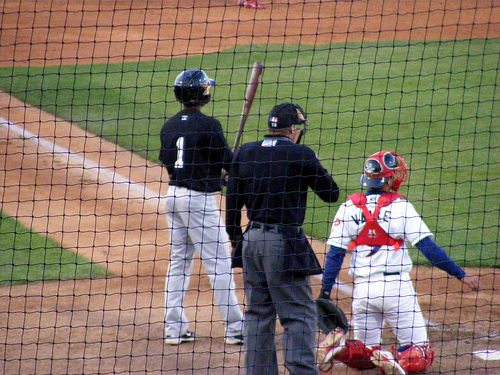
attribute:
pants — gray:
[235, 219, 321, 373]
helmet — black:
[167, 66, 226, 112]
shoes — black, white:
[160, 327, 241, 348]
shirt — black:
[219, 136, 344, 236]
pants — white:
[343, 271, 435, 347]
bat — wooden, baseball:
[227, 53, 277, 154]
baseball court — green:
[183, 14, 498, 250]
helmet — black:
[170, 62, 217, 105]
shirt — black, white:
[153, 109, 231, 196]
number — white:
[170, 133, 186, 171]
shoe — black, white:
[164, 329, 200, 349]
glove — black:
[313, 296, 354, 336]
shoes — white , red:
[319, 325, 400, 372]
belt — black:
[242, 216, 309, 237]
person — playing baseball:
[153, 58, 245, 354]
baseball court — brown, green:
[2, 2, 496, 372]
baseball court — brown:
[15, 127, 118, 217]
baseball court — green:
[342, 56, 478, 143]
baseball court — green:
[352, 51, 466, 136]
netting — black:
[13, 16, 483, 366]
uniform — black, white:
[153, 107, 243, 332]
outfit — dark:
[222, 136, 340, 365]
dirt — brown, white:
[72, 152, 139, 197]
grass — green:
[324, 54, 476, 132]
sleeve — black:
[298, 147, 337, 203]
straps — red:
[347, 190, 400, 253]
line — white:
[4, 115, 162, 208]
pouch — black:
[270, 224, 325, 281]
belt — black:
[247, 221, 300, 231]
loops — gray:
[244, 220, 294, 232]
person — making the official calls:
[225, 101, 334, 359]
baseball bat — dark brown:
[234, 58, 259, 162]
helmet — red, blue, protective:
[367, 150, 406, 197]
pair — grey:
[242, 222, 331, 362]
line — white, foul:
[0, 99, 168, 235]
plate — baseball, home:
[481, 346, 485, 357]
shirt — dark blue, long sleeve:
[220, 136, 332, 270]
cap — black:
[265, 100, 319, 131]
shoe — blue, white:
[162, 327, 202, 349]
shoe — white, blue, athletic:
[216, 329, 248, 344]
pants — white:
[343, 268, 428, 352]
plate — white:
[464, 341, 498, 366]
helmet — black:
[161, 67, 222, 109]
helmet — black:
[168, 64, 217, 111]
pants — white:
[153, 184, 245, 338]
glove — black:
[305, 289, 355, 332]